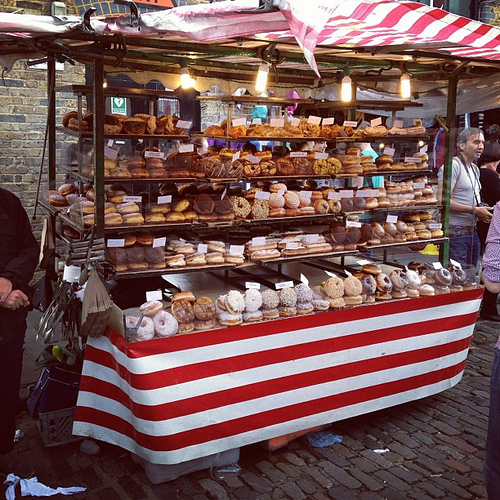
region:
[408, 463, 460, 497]
the floor is tile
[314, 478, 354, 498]
the floor is tile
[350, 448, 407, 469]
the floor is tile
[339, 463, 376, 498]
the floor is tile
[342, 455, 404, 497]
the floor is tile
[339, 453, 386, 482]
the floor is tile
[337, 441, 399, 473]
the floor is tile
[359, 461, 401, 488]
the floor is tile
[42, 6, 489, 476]
Kiosk on sidewalk selling doughnuts.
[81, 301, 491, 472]
Red and white skirt around bottom of kiosk.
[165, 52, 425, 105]
Lights hanging from top to kiosk.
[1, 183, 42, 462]
Person dressed in black standing beside kiosk.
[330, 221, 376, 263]
A tray of chocolate doughnuts.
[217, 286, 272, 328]
Doughnuts sprinkled with coconut.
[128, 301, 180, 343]
Dougnuts sprinkled with powered sugar.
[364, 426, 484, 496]
A brick paved sidewalk.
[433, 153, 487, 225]
Man dressed in white t-shirt.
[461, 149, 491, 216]
Man wearing camera over shoulder.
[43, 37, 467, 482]
an outdoor doughnut cart on the street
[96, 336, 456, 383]
red striped fabric on the doughnut cart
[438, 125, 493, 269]
a man with a camera around his neck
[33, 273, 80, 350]
kitchen tools for grabbing doughnuts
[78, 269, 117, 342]
bags to put the doughnuts in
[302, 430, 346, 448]
trash under the doughnut cart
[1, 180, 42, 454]
a person standing next to the doughnut cart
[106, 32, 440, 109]
a string of lights on the doughnut cart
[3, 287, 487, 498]
a brick road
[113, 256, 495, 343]
doughnuts on the cart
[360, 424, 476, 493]
cobblestone street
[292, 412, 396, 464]
garbage on ground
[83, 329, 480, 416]
red and white striped covering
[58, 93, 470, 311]
shelves of donuts and pastries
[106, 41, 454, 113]
strip of light bulbs hanging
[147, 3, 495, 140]
red and white striped awning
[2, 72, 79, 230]
old style grey brick building in background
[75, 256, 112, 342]
brown paper bags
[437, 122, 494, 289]
man in grey shirt and blue jeans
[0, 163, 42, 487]
person standing in black clothing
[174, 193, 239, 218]
chocolate covered dougnuts in the case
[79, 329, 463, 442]
red and white table cloth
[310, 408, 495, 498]
table under brick sidewalk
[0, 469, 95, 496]
litter on the ground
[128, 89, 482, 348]
assorted doughnuts to sell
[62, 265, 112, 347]
bags to put doughnuts in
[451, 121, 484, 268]
man standing near stand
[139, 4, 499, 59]
red and white awning covering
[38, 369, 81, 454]
storage bins stacked in corner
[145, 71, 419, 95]
four lights on top